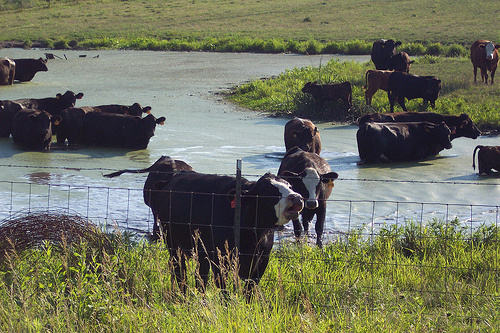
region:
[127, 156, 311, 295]
cow at the fence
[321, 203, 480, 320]
fence is made of wire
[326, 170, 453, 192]
barbed wire running along the top of the fence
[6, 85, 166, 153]
cows are in the water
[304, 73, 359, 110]
calf standing at the edge of the water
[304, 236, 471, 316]
grass growing by the water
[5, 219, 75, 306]
roll of wire by the fence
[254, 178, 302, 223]
cow is mooing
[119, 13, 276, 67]
field across the water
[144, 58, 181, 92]
water is calm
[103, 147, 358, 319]
black and white cows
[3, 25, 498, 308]
a herd of cows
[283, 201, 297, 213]
mouth is open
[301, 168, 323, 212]
thick white stripe on the face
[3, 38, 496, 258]
shallow body of water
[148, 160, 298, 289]
cow standing on the grass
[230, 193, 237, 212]
tag in the ear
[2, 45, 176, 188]
cows in the water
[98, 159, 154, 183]
tail is swishing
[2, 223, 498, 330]
tall green grass on the ground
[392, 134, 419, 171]
the cow is in the water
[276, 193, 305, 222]
the cows mouth is open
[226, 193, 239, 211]
the tag is red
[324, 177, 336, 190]
the tag is yellow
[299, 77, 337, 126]
the calf is by the water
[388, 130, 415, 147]
the cow is black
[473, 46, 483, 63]
the cow is brown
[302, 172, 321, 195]
the cows face is white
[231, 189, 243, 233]
the t post is dark green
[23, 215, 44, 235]
the barbed wire is rusty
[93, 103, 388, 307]
two cows in water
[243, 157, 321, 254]
face of the cow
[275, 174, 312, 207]
white color in face of cow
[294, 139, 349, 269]
a cow in the water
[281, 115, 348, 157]
a cow inside the water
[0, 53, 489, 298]
a wide group of cows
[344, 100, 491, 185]
a cow bathing in water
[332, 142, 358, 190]
shadow in the water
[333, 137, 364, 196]
shadow of the cow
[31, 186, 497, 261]
a small fence around water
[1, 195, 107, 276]
the roll of barb wie by the fence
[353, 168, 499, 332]
the mesh barbed wire fence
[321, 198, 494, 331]
the metal mesh on the fence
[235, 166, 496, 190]
the strand of barbed wire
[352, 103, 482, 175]
the catle in the water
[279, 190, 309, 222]
the open mouth of the cow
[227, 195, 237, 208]
the red tag on the ear of the cow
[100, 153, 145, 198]
the tail of the cow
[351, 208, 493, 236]
the ripples in the water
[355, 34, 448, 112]
the cattle on the grass bank